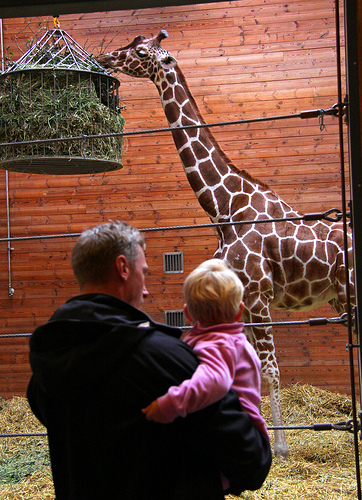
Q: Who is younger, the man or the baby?
A: The baby is younger than the man.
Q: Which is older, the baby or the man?
A: The man is older than the baby.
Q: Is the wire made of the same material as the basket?
A: Yes, both the wire and the basket are made of metal.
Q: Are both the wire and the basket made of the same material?
A: Yes, both the wire and the basket are made of metal.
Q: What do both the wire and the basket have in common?
A: The material, both the wire and the basket are metallic.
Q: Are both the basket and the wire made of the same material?
A: Yes, both the basket and the wire are made of metal.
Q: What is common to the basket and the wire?
A: The material, both the basket and the wire are metallic.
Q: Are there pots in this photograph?
A: No, there are no pots.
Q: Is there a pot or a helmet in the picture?
A: No, there are no pots or helmets.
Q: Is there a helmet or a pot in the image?
A: No, there are no pots or helmets.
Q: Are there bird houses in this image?
A: No, there are no bird houses.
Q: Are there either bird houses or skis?
A: No, there are no bird houses or skis.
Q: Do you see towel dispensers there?
A: No, there are no towel dispensers.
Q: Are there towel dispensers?
A: No, there are no towel dispensers.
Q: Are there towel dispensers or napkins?
A: No, there are no towel dispensers or napkins.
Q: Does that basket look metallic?
A: Yes, the basket is metallic.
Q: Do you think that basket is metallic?
A: Yes, the basket is metallic.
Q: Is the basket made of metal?
A: Yes, the basket is made of metal.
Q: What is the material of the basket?
A: The basket is made of metal.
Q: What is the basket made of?
A: The basket is made of metal.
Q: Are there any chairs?
A: No, there are no chairs.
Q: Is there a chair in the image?
A: No, there are no chairs.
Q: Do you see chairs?
A: No, there are no chairs.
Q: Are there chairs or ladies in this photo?
A: No, there are no chairs or ladies.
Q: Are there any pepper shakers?
A: No, there are no pepper shakers.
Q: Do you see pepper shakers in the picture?
A: No, there are no pepper shakers.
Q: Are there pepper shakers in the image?
A: No, there are no pepper shakers.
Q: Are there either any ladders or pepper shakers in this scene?
A: No, there are no pepper shakers or ladders.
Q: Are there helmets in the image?
A: No, there are no helmets.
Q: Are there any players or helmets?
A: No, there are no helmets or players.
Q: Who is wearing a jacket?
A: The man is wearing a jacket.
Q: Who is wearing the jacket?
A: The man is wearing a jacket.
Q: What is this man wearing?
A: The man is wearing a jacket.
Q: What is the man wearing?
A: The man is wearing a jacket.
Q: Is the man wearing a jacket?
A: Yes, the man is wearing a jacket.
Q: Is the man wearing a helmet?
A: No, the man is wearing a jacket.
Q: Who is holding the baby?
A: The man is holding the baby.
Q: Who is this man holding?
A: The man is holding the baby.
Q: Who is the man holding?
A: The man is holding the baby.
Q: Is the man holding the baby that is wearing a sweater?
A: Yes, the man is holding the baby.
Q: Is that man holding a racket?
A: No, the man is holding the baby.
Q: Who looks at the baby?
A: The man looks at the baby.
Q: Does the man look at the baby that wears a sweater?
A: Yes, the man looks at the baby.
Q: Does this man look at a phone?
A: No, the man looks at the baby.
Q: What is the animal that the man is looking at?
A: The animal is a giraffe.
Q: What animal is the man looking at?
A: The man is looking at the giraffe.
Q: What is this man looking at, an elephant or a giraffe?
A: The man is looking at a giraffe.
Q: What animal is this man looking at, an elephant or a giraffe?
A: The man is looking at a giraffe.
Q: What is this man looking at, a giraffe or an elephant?
A: The man is looking at a giraffe.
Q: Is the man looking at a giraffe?
A: Yes, the man is looking at a giraffe.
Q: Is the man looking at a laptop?
A: No, the man is looking at a giraffe.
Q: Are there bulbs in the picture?
A: No, there are no bulbs.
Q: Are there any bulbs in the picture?
A: No, there are no bulbs.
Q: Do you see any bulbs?
A: No, there are no bulbs.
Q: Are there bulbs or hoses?
A: No, there are no bulbs or hoses.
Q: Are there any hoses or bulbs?
A: No, there are no bulbs or hoses.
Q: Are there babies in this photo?
A: Yes, there is a baby.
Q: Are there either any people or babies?
A: Yes, there is a baby.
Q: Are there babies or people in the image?
A: Yes, there is a baby.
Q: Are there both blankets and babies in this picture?
A: No, there is a baby but no blankets.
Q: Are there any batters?
A: No, there are no batters.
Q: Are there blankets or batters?
A: No, there are no batters or blankets.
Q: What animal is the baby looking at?
A: The baby is looking at the giraffe.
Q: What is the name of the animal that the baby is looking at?
A: The animal is a giraffe.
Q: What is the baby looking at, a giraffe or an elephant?
A: The baby is looking at a giraffe.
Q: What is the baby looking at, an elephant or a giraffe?
A: The baby is looking at a giraffe.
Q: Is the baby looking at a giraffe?
A: Yes, the baby is looking at a giraffe.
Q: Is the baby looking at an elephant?
A: No, the baby is looking at a giraffe.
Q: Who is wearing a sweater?
A: The baby is wearing a sweater.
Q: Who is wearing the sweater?
A: The baby is wearing a sweater.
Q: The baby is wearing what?
A: The baby is wearing a sweater.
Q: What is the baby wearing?
A: The baby is wearing a sweater.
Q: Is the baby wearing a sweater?
A: Yes, the baby is wearing a sweater.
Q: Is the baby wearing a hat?
A: No, the baby is wearing a sweater.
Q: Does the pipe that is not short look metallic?
A: Yes, the pipe is metallic.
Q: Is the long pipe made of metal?
A: Yes, the pipe is made of metal.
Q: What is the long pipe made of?
A: The pipe is made of metal.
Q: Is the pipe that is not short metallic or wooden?
A: The pipe is metallic.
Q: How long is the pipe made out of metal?
A: The pipe is long.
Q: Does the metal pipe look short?
A: No, the pipe is long.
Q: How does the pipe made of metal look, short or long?
A: The pipe is long.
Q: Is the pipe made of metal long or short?
A: The pipe is long.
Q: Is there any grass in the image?
A: Yes, there is grass.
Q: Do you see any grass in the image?
A: Yes, there is grass.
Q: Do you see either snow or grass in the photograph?
A: Yes, there is grass.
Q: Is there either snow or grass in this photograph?
A: Yes, there is grass.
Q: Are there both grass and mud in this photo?
A: No, there is grass but no mud.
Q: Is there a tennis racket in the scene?
A: No, there are no rackets.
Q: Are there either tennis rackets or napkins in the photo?
A: No, there are no tennis rackets or napkins.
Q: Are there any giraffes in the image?
A: Yes, there is a giraffe.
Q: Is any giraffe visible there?
A: Yes, there is a giraffe.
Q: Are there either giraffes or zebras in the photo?
A: Yes, there is a giraffe.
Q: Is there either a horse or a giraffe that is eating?
A: Yes, the giraffe is eating.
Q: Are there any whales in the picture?
A: No, there are no whales.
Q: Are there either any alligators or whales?
A: No, there are no whales or alligators.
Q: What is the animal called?
A: The animal is a giraffe.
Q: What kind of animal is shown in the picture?
A: The animal is a giraffe.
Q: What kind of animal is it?
A: The animal is a giraffe.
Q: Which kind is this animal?
A: This is a giraffe.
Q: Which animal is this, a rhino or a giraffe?
A: This is a giraffe.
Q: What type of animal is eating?
A: The animal is a giraffe.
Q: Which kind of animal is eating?
A: The animal is a giraffe.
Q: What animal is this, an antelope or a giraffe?
A: This is a giraffe.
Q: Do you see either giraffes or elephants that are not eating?
A: No, there is a giraffe but it is eating.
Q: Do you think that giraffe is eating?
A: Yes, the giraffe is eating.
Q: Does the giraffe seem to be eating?
A: Yes, the giraffe is eating.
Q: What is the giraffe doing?
A: The giraffe is eating.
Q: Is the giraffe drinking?
A: No, the giraffe is eating.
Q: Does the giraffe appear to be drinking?
A: No, the giraffe is eating.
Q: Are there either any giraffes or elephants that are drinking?
A: No, there is a giraffe but it is eating.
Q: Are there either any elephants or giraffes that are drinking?
A: No, there is a giraffe but it is eating.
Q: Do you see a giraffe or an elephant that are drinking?
A: No, there is a giraffe but it is eating.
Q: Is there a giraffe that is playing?
A: No, there is a giraffe but it is eating.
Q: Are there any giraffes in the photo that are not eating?
A: No, there is a giraffe but it is eating.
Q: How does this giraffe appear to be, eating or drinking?
A: The giraffe is eating.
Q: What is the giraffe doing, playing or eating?
A: The giraffe is eating.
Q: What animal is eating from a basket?
A: The giraffe is eating from a basket.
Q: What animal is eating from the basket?
A: The giraffe is eating from a basket.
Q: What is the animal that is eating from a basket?
A: The animal is a giraffe.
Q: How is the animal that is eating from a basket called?
A: The animal is a giraffe.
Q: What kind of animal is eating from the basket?
A: The animal is a giraffe.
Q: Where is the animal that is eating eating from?
A: The giraffe is eating from a basket.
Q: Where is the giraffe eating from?
A: The giraffe is eating from a basket.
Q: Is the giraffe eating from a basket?
A: Yes, the giraffe is eating from a basket.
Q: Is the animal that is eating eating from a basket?
A: Yes, the giraffe is eating from a basket.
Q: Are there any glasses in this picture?
A: No, there are no glasses.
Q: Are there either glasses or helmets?
A: No, there are no glasses or helmets.